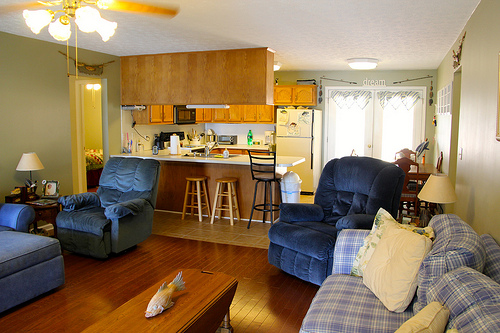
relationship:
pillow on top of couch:
[368, 233, 427, 306] [307, 224, 498, 331]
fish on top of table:
[146, 273, 188, 318] [83, 269, 243, 331]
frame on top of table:
[43, 180, 61, 199] [16, 199, 62, 235]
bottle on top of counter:
[247, 130, 254, 145] [211, 144, 270, 151]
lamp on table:
[17, 152, 44, 199] [16, 199, 62, 235]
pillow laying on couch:
[368, 233, 427, 306] [307, 224, 498, 331]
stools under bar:
[184, 176, 238, 222] [132, 150, 300, 169]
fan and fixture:
[5, 2, 181, 23] [28, 11, 117, 42]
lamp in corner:
[414, 172, 453, 226] [388, 155, 481, 244]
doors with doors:
[325, 90, 424, 168] [325, 90, 425, 160]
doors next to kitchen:
[325, 90, 424, 168] [119, 42, 308, 212]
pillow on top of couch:
[356, 233, 427, 312] [307, 224, 498, 331]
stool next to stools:
[245, 147, 283, 229] [184, 176, 238, 222]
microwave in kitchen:
[175, 105, 195, 123] [119, 42, 308, 212]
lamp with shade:
[17, 152, 44, 199] [15, 153, 43, 170]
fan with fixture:
[5, 2, 181, 23] [28, 11, 117, 42]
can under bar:
[281, 173, 300, 203] [132, 150, 300, 169]